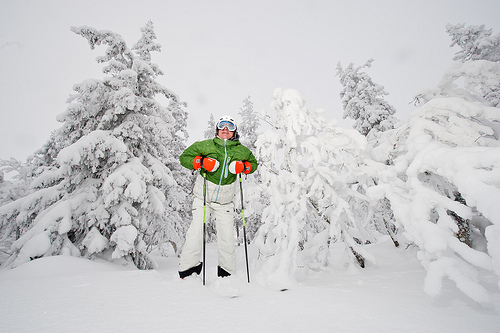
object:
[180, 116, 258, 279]
man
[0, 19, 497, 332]
snow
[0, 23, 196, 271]
tree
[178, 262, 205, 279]
shoe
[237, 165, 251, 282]
ski pole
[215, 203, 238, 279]
leg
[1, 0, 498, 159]
sky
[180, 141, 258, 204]
jacket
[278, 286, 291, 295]
ski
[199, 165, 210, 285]
ski pole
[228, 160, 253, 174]
glove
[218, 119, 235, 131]
goggles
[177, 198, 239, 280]
pants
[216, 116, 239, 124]
helmet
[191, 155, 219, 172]
glove